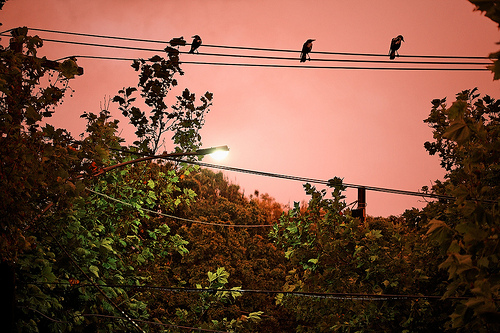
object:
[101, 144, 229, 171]
street light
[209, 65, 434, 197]
incorrect sentence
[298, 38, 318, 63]
drop cloth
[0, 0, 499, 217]
sky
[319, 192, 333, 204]
leaves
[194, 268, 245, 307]
leaves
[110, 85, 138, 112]
leaves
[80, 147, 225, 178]
branch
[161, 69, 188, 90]
leaves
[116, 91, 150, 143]
branch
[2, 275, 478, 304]
telephone wire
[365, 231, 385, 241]
leaf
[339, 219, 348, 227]
leaf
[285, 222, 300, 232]
leaf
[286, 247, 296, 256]
leaf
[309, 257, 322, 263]
leaf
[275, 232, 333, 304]
branch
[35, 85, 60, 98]
leaves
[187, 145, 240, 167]
light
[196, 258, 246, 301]
foilage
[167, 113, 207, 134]
leaves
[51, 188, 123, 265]
branch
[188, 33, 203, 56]
bird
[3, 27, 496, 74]
telephone wire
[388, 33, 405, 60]
bird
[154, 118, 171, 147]
branch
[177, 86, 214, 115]
leaves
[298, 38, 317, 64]
bird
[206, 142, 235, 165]
sun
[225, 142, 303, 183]
cow